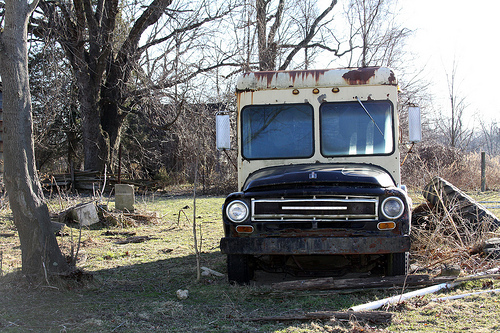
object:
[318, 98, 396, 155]
windshield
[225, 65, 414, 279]
truck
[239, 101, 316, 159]
windshield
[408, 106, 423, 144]
mirror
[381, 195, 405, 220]
headlight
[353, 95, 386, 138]
windshield wiper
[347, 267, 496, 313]
pole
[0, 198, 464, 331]
ground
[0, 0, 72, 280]
tree trunk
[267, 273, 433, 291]
log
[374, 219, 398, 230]
light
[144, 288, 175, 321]
grass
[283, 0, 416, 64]
branches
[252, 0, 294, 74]
tree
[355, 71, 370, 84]
metal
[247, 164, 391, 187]
hood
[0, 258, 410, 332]
shadow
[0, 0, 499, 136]
sky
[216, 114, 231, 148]
mirror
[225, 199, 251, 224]
headlight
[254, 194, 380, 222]
grill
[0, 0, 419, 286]
trees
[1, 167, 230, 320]
yard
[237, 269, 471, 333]
articles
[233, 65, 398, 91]
top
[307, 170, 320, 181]
emblem